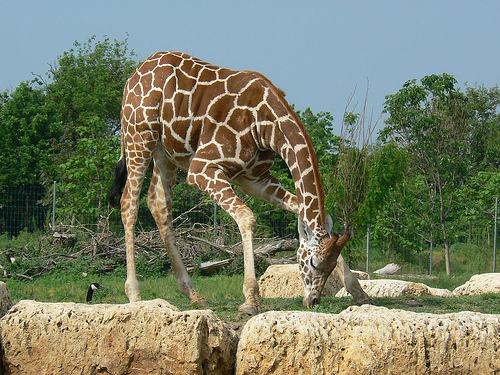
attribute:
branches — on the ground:
[21, 214, 235, 275]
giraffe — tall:
[111, 44, 376, 311]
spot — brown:
[168, 65, 201, 93]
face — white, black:
[89, 278, 102, 291]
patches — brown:
[167, 90, 190, 119]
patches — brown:
[169, 117, 190, 138]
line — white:
[185, 87, 197, 140]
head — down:
[293, 229, 348, 309]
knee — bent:
[240, 202, 259, 240]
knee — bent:
[323, 205, 333, 241]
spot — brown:
[215, 123, 242, 160]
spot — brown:
[234, 79, 266, 108]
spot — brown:
[175, 91, 191, 118]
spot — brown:
[151, 67, 172, 88]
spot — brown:
[125, 90, 144, 110]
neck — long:
[279, 101, 327, 228]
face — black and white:
[90, 284, 107, 293]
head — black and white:
[90, 279, 103, 293]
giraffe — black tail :
[94, 150, 134, 213]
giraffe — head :
[280, 197, 344, 314]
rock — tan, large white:
[257, 249, 429, 309]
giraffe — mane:
[284, 82, 329, 223]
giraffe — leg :
[183, 145, 281, 319]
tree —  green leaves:
[424, 96, 454, 126]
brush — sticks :
[24, 210, 291, 284]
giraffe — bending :
[70, 31, 356, 323]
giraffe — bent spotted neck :
[254, 88, 328, 218]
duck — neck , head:
[83, 275, 111, 302]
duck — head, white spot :
[90, 280, 97, 299]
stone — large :
[1, 283, 235, 372]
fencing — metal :
[38, 180, 483, 286]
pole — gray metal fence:
[358, 225, 373, 270]